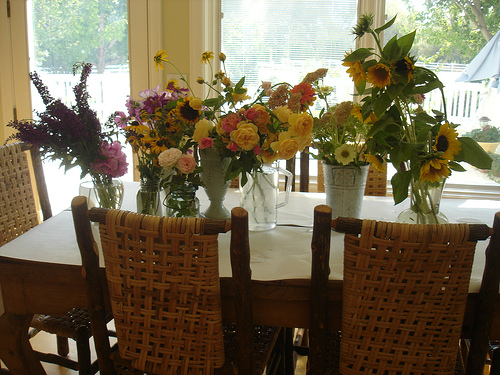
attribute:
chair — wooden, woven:
[67, 201, 293, 373]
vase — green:
[198, 151, 238, 222]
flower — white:
[152, 138, 186, 164]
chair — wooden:
[284, 186, 498, 348]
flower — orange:
[335, 49, 403, 95]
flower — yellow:
[287, 36, 499, 217]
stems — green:
[97, 177, 122, 211]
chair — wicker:
[53, 160, 273, 323]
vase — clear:
[160, 186, 208, 221]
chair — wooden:
[70, 196, 256, 370]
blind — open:
[217, 6, 354, 111]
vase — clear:
[239, 160, 293, 230]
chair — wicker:
[300, 203, 467, 366]